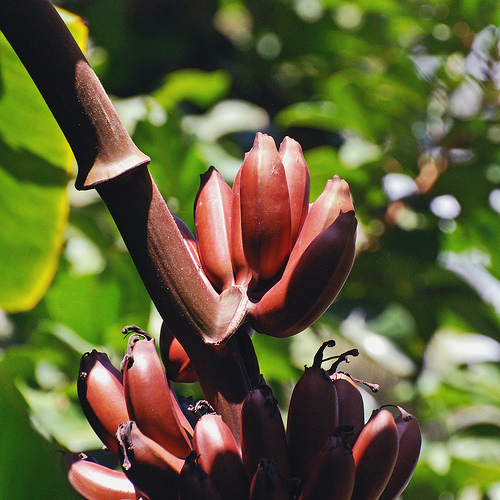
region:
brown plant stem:
[38, 40, 143, 192]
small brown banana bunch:
[178, 113, 363, 331]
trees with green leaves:
[312, 21, 498, 175]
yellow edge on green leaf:
[45, 127, 79, 306]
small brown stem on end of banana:
[117, 314, 156, 346]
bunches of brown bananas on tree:
[30, 113, 447, 498]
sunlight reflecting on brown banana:
[99, 337, 159, 391]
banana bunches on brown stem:
[25, 27, 416, 497]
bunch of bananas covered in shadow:
[137, 393, 424, 498]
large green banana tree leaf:
[0, 126, 52, 303]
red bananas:
[181, 120, 386, 341]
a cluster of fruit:
[180, 122, 377, 356]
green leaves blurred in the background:
[312, 26, 489, 173]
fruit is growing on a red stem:
[40, 54, 229, 339]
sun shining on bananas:
[173, 121, 398, 331]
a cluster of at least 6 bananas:
[185, 121, 392, 340]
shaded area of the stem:
[0, 5, 95, 84]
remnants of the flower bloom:
[98, 307, 166, 373]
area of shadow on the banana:
[281, 358, 435, 496]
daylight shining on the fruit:
[172, 111, 417, 491]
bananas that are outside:
[32, 97, 490, 499]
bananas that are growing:
[58, 124, 432, 499]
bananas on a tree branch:
[30, 140, 457, 499]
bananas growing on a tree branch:
[30, 102, 418, 492]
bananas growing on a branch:
[8, 133, 473, 496]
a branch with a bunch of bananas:
[51, 125, 496, 495]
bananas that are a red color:
[5, 136, 402, 499]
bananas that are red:
[39, 137, 446, 497]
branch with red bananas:
[28, 134, 450, 498]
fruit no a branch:
[8, 122, 497, 482]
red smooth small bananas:
[171, 124, 378, 359]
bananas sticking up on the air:
[164, 117, 384, 349]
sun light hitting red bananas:
[49, 314, 249, 498]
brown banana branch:
[7, 10, 299, 377]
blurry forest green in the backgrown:
[357, 27, 498, 290]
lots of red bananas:
[11, 120, 463, 496]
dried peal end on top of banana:
[101, 313, 177, 407]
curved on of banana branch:
[186, 269, 272, 364]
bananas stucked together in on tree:
[175, 112, 397, 379]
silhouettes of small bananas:
[232, 357, 344, 499]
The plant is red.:
[25, 154, 440, 499]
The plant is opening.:
[112, 320, 172, 400]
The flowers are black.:
[308, 331, 371, 381]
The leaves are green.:
[273, 7, 395, 155]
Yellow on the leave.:
[16, 165, 86, 315]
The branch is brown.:
[90, 148, 230, 368]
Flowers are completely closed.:
[195, 119, 355, 341]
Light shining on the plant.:
[175, 177, 247, 334]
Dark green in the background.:
[101, 0, 269, 97]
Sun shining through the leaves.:
[378, 57, 495, 227]